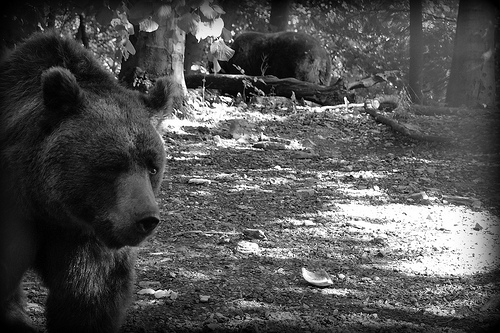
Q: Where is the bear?
A: In the woods.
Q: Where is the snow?
A: On the ground.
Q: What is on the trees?
A: Leaves.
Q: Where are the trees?
A: In the woods.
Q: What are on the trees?
A: Leaves.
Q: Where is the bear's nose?
A: On it's face.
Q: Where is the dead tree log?
A: On the ground.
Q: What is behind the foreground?
A: Tree trunk behind foreground bear.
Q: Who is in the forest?
A: Two brown bears in the forest.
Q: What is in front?
A: The face of a bear.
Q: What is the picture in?
A: The picture is black and white.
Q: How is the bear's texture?
A: The bear is furry.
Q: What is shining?
A: The sun is on the ground.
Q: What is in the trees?
A: Bears.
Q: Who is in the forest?
A: A bear.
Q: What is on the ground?
A: A tree trunk.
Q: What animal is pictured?
A: Bear.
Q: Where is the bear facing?
A: Toward the camera.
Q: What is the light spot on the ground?
A: Sunlight.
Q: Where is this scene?
A: Woods.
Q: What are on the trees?
A: Leaves.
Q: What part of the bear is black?
A: Nose.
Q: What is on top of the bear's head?
A: Ears.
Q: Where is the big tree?
A: Behind the bear.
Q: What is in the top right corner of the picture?
A: Tree.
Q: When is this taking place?
A: Daytime.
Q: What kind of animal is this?
A: Bear.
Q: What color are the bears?
A: Brown.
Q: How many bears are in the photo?
A: Two.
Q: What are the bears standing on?
A: Ground.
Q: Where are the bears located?
A: Forest.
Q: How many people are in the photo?
A: None.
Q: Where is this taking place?
A: In the woods.